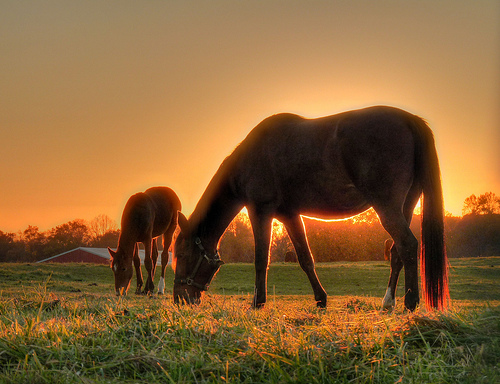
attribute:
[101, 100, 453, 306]
horses — eating, brown, standing, large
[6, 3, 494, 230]
sky — clear, orange, cloudy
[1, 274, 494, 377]
grass — green, long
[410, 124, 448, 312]
tail — long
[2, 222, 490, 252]
trees — far, in background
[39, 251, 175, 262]
roof — white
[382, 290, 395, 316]
foot — white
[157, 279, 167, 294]
foot — white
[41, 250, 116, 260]
building — red, distant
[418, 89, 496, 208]
sunset — yellow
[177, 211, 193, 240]
ears — pointed